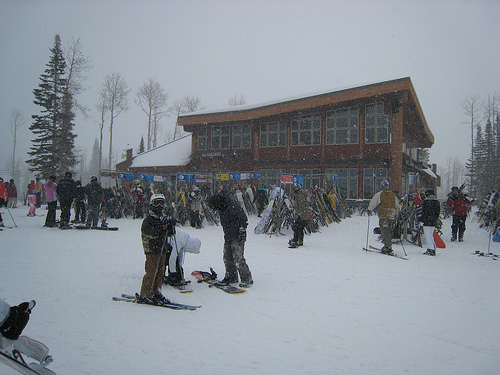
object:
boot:
[165, 272, 184, 285]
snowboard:
[170, 279, 195, 294]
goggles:
[153, 198, 167, 205]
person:
[368, 177, 403, 254]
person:
[138, 182, 193, 317]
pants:
[140, 251, 171, 296]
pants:
[422, 223, 439, 256]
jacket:
[44, 174, 60, 227]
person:
[42, 174, 52, 222]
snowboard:
[43, 222, 69, 228]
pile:
[250, 171, 356, 247]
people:
[208, 181, 448, 283]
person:
[287, 181, 311, 248]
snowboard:
[75, 225, 118, 230]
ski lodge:
[103, 75, 440, 224]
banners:
[115, 172, 261, 182]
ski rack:
[173, 182, 328, 229]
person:
[206, 191, 254, 290]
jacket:
[164, 232, 200, 271]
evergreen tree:
[27, 32, 78, 182]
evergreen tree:
[463, 94, 500, 211]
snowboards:
[257, 177, 352, 242]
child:
[26, 188, 38, 217]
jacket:
[44, 180, 59, 203]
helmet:
[149, 192, 167, 203]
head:
[149, 193, 167, 211]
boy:
[139, 191, 174, 307]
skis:
[114, 294, 202, 311]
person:
[159, 232, 202, 288]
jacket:
[212, 198, 250, 242]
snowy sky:
[0, 0, 500, 139]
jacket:
[367, 190, 404, 220]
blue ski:
[138, 193, 176, 303]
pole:
[172, 227, 187, 290]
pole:
[146, 230, 171, 298]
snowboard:
[191, 269, 246, 294]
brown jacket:
[367, 189, 402, 219]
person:
[28, 188, 38, 217]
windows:
[193, 97, 394, 146]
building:
[112, 75, 438, 216]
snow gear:
[24, 213, 45, 218]